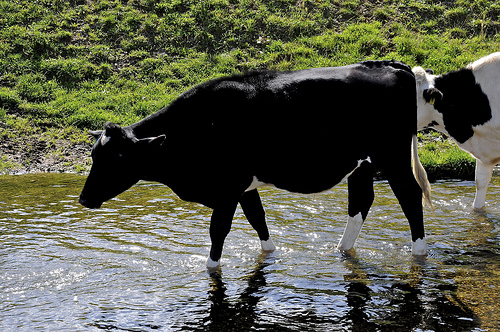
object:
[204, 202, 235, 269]
leg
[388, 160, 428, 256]
leg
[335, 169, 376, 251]
leg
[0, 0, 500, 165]
grass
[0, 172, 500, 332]
water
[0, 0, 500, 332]
ground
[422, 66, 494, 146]
black marking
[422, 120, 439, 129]
black marking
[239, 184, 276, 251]
leg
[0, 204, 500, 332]
reflection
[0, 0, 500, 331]
floor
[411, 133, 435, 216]
white hair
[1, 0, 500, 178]
riverbank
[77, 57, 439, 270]
animal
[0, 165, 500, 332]
stream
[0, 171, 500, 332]
ripple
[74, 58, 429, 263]
markings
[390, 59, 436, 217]
tail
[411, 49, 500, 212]
bovine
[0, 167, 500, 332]
brook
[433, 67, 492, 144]
spot